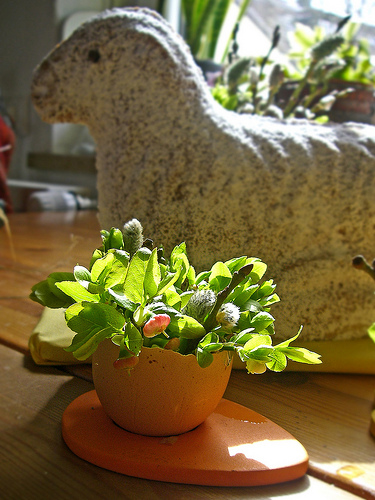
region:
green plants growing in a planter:
[58, 227, 280, 387]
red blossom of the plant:
[134, 310, 170, 340]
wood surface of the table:
[20, 450, 79, 484]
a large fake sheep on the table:
[31, 15, 371, 237]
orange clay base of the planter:
[79, 399, 278, 478]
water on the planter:
[210, 389, 271, 430]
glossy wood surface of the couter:
[29, 215, 91, 266]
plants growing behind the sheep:
[205, 22, 360, 119]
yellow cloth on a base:
[257, 334, 373, 382]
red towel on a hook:
[0, 114, 30, 224]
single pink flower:
[142, 315, 181, 342]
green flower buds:
[212, 304, 247, 327]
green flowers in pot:
[127, 255, 280, 357]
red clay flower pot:
[73, 338, 256, 432]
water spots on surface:
[229, 393, 365, 479]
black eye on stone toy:
[75, 44, 116, 69]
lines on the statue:
[225, 129, 343, 169]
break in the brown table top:
[317, 458, 355, 490]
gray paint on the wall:
[12, 11, 45, 29]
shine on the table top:
[35, 212, 75, 238]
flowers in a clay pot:
[28, 221, 249, 443]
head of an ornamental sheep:
[23, 15, 206, 151]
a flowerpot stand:
[60, 377, 312, 484]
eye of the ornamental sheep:
[81, 47, 107, 69]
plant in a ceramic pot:
[36, 233, 316, 380]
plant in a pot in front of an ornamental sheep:
[32, 233, 255, 452]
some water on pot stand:
[215, 393, 275, 435]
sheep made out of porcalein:
[34, 22, 373, 310]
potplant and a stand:
[41, 324, 346, 499]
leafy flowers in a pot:
[42, 232, 340, 414]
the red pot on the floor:
[97, 328, 229, 434]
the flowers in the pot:
[39, 231, 311, 366]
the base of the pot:
[64, 390, 339, 496]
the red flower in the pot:
[142, 311, 174, 338]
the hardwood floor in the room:
[2, 202, 374, 498]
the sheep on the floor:
[44, 16, 373, 320]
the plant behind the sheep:
[225, 47, 339, 115]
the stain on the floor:
[325, 454, 358, 486]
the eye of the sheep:
[87, 47, 105, 65]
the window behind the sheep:
[219, 1, 367, 85]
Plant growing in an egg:
[27, 216, 240, 482]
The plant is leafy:
[55, 236, 240, 357]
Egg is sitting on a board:
[85, 421, 219, 476]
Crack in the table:
[316, 457, 361, 497]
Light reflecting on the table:
[235, 412, 314, 497]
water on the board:
[223, 398, 265, 433]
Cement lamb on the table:
[32, 29, 286, 202]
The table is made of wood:
[8, 381, 92, 491]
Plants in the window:
[209, 22, 364, 114]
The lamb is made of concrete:
[14, 15, 245, 145]